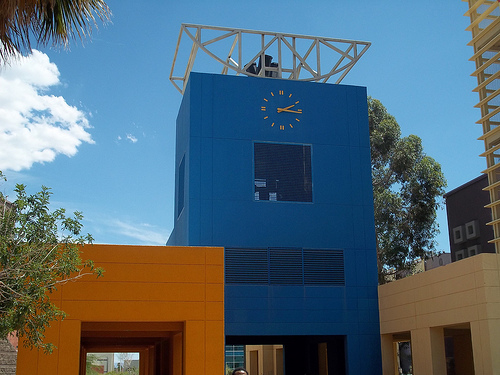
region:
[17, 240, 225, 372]
Orange front of building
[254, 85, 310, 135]
Clock on blue building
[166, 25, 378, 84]
Antenna/Satellite area on blue building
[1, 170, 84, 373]
Tree in front of orange building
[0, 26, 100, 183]
Cloud in the sky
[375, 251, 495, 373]
Beige building next to blue building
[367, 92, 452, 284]
Tree in the background of the blue building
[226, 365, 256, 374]
Top of man's head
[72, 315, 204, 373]
Breezeway through orange building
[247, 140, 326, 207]
Ventilation window of blue building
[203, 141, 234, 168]
dark blue paint on wall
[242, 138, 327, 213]
large opening in front of building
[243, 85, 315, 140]
gold clock on the wall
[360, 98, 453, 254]
tree at side of building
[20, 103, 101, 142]
puff of clouds floating by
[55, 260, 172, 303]
deep gold color on building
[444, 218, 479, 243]
white color on windows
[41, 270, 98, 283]
thin branches on tree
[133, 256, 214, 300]
squares on gold building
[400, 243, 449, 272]
roof of houses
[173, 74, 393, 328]
blue color building with clock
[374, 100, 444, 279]
tree behind the blue color building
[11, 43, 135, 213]
blue color sky with clouds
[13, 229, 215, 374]
tree in front of the yellow color building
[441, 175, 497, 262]
brown color building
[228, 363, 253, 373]
head of the person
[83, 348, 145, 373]
glass inside the building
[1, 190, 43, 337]
trees with branches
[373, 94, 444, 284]
trees with branches behind the blue building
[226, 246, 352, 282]
window of the building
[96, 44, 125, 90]
this is the sky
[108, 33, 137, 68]
the sky is blue in color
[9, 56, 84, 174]
the sky has clouds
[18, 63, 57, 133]
the clouds are white in color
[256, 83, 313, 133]
this is a clock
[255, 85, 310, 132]
the clock is small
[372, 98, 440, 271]
this is a tree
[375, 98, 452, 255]
the tree is short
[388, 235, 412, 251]
the leaves are green in color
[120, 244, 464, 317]
these are some buildings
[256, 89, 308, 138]
a small wal lclock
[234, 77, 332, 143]
a beautiful wall clock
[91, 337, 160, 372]
a gap inside the wall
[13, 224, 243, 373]
a brown color wall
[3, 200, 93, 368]
a part of the trees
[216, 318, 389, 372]
a gap in blue wall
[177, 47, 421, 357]
a beautiful blue pillar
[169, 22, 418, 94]
a iron stand on top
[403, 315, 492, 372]
windows in the wall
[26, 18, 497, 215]
a clear view of sky